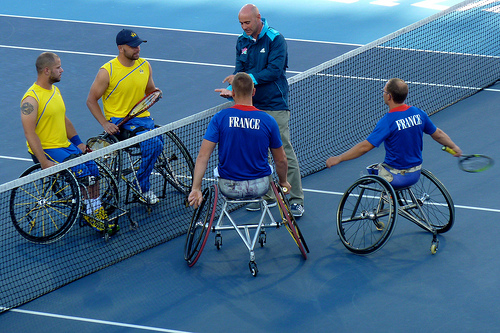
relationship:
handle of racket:
[442, 142, 460, 159] [439, 144, 495, 174]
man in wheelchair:
[188, 72, 295, 209] [183, 182, 307, 274]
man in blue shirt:
[324, 75, 463, 191] [365, 102, 439, 171]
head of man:
[230, 72, 255, 105] [188, 72, 295, 209]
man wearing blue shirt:
[337, 73, 460, 223] [365, 102, 441, 183]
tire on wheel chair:
[173, 175, 236, 281] [214, 132, 305, 286]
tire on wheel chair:
[264, 182, 320, 259] [214, 132, 305, 286]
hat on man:
[110, 26, 145, 52] [71, 27, 172, 196]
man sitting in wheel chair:
[186, 70, 293, 210] [195, 184, 301, 264]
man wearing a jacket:
[215, 4, 304, 221] [233, 19, 290, 111]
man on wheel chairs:
[324, 75, 463, 191] [188, 169, 457, 275]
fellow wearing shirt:
[16, 50, 85, 169] [101, 55, 150, 120]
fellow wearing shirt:
[69, 49, 197, 139] [101, 55, 150, 120]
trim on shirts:
[222, 99, 411, 117] [205, 100, 429, 169]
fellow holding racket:
[16, 50, 122, 233] [98, 88, 163, 140]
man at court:
[324, 75, 463, 191] [0, 12, 499, 328]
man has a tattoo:
[19, 51, 115, 233] [19, 101, 35, 116]